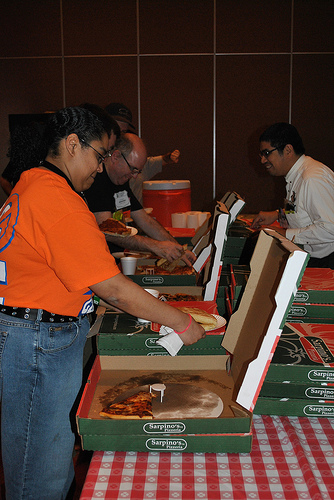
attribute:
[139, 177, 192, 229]
cooler — orange, white, large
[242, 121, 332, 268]
man — smiling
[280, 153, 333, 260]
shirt — white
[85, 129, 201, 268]
man — bald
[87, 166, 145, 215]
tshirt — black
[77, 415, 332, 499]
tablecloth — red, white, checkered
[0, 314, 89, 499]
jeans — blue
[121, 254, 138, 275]
cup — white, syrofoam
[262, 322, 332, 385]
pizza box — closed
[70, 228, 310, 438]
pizza box — open, almost empty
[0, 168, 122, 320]
tshirt — orange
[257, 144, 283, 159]
glasses — black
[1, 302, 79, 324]
belt — black, studded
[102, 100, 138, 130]
hat — black, brown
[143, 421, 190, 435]
logo — white